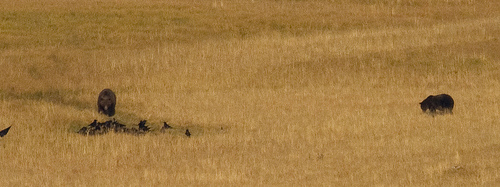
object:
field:
[0, 0, 499, 187]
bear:
[94, 88, 118, 119]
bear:
[417, 93, 455, 116]